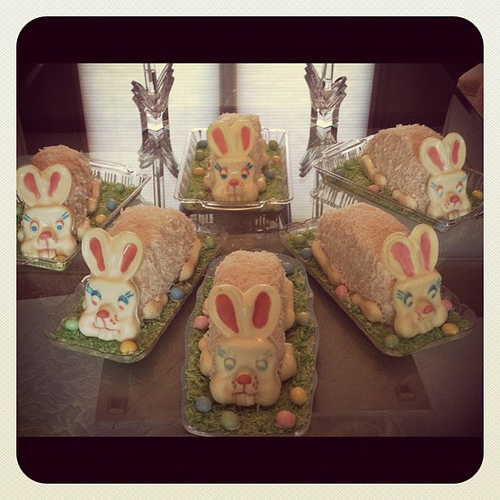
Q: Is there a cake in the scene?
A: Yes, there is a cake.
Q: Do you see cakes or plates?
A: Yes, there is a cake.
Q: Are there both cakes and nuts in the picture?
A: No, there is a cake but no nuts.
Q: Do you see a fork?
A: No, there are no forks.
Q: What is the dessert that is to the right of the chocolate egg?
A: The dessert is a cake.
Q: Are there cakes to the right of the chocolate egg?
A: Yes, there is a cake to the right of the egg.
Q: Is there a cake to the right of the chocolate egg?
A: Yes, there is a cake to the right of the egg.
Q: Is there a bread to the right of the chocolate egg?
A: No, there is a cake to the right of the egg.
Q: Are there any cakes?
A: Yes, there is a cake.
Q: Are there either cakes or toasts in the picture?
A: Yes, there is a cake.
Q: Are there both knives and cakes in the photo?
A: No, there is a cake but no knives.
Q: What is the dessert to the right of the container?
A: The dessert is a cake.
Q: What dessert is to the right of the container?
A: The dessert is a cake.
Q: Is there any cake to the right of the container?
A: Yes, there is a cake to the right of the container.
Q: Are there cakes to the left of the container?
A: No, the cake is to the right of the container.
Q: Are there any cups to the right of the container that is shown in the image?
A: No, there is a cake to the right of the container.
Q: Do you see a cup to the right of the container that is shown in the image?
A: No, there is a cake to the right of the container.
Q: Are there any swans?
A: No, there are no swans.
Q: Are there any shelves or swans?
A: No, there are no swans or shelves.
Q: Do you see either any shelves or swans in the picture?
A: No, there are no swans or shelves.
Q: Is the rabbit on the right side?
A: Yes, the rabbit is on the right of the image.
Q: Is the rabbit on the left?
A: No, the rabbit is on the right of the image.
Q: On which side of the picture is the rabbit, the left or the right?
A: The rabbit is on the right of the image.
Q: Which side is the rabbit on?
A: The rabbit is on the right of the image.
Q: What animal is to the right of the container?
A: The animal is a rabbit.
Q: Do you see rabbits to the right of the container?
A: Yes, there is a rabbit to the right of the container.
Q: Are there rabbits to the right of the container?
A: Yes, there is a rabbit to the right of the container.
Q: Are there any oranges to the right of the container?
A: No, there is a rabbit to the right of the container.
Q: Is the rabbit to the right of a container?
A: Yes, the rabbit is to the right of a container.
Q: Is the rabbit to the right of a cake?
A: Yes, the rabbit is to the right of a cake.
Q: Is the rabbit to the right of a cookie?
A: No, the rabbit is to the right of a cake.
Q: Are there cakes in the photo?
A: Yes, there is a cake.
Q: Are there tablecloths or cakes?
A: Yes, there is a cake.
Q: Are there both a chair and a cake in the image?
A: No, there is a cake but no chairs.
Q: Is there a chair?
A: No, there are no chairs.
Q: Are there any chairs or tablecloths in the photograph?
A: No, there are no chairs or tablecloths.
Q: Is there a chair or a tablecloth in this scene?
A: No, there are no chairs or tablecloths.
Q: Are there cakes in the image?
A: Yes, there is a cake.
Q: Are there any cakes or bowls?
A: Yes, there is a cake.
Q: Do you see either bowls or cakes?
A: Yes, there is a cake.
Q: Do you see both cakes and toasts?
A: No, there is a cake but no toasts.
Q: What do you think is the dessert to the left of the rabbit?
A: The dessert is a cake.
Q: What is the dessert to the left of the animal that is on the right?
A: The dessert is a cake.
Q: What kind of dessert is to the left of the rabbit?
A: The dessert is a cake.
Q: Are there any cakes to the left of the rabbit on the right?
A: Yes, there is a cake to the left of the rabbit.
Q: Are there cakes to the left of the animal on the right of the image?
A: Yes, there is a cake to the left of the rabbit.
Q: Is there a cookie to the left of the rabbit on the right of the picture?
A: No, there is a cake to the left of the rabbit.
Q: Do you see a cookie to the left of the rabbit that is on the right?
A: No, there is a cake to the left of the rabbit.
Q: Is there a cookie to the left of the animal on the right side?
A: No, there is a cake to the left of the rabbit.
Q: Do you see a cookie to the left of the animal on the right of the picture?
A: No, there is a cake to the left of the rabbit.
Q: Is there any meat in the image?
A: No, there is no meat.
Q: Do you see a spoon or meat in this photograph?
A: No, there are no meat or spoons.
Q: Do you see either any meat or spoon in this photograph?
A: No, there are no meat or spoons.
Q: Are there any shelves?
A: No, there are no shelves.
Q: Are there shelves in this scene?
A: No, there are no shelves.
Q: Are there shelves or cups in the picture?
A: No, there are no shelves or cups.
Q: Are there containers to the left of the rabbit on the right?
A: Yes, there is a container to the left of the rabbit.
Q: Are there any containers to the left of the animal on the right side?
A: Yes, there is a container to the left of the rabbit.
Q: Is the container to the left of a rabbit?
A: Yes, the container is to the left of a rabbit.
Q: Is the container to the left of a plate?
A: No, the container is to the left of a rabbit.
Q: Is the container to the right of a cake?
A: No, the container is to the left of a cake.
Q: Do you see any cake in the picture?
A: Yes, there is a cake.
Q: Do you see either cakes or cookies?
A: Yes, there is a cake.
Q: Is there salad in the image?
A: No, there is no salad.